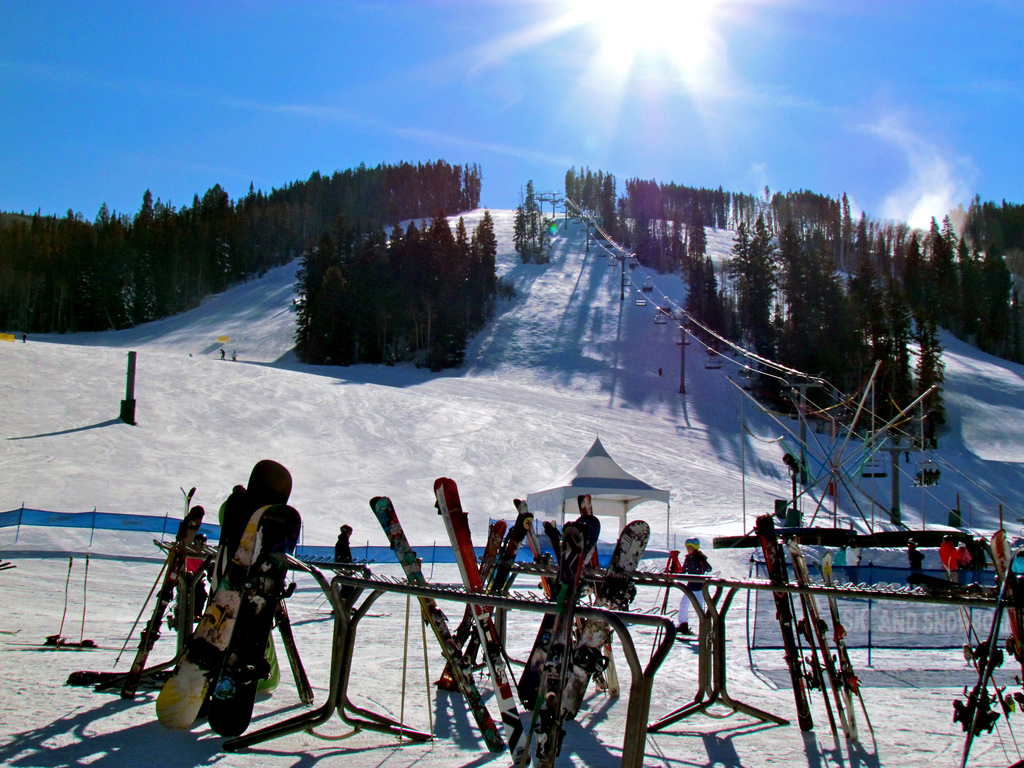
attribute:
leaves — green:
[388, 240, 433, 285]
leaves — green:
[885, 326, 904, 349]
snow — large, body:
[1, 197, 1020, 540]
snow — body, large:
[18, 316, 490, 473]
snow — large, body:
[3, 236, 692, 494]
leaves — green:
[854, 212, 1023, 353]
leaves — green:
[775, 276, 811, 328]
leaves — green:
[742, 265, 926, 400]